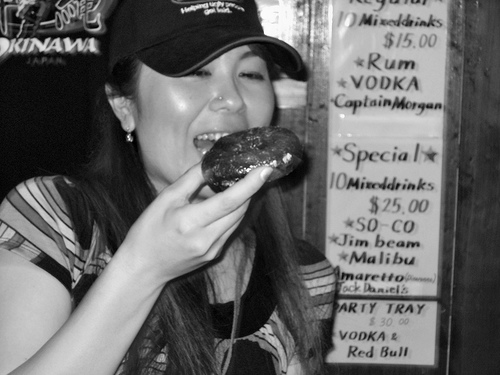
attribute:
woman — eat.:
[2, 1, 340, 372]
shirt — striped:
[2, 170, 338, 373]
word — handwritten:
[340, 140, 422, 175]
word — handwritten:
[347, 174, 387, 191]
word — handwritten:
[373, 231, 420, 249]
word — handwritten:
[348, 249, 417, 266]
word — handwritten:
[333, 264, 403, 281]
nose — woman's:
[208, 69, 250, 117]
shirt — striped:
[2, 174, 358, 366]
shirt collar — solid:
[195, 235, 284, 342]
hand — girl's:
[21, 156, 274, 373]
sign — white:
[304, 0, 478, 372]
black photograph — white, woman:
[4, 0, 494, 362]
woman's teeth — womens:
[193, 131, 233, 157]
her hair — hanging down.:
[80, 84, 362, 365]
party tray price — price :
[363, 317, 419, 331]